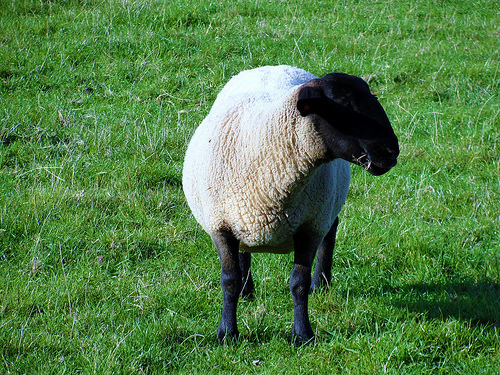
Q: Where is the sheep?
A: In grass.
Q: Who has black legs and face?
A: Sheep.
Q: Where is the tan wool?
A: On sheep.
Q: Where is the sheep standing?
A: In grass field.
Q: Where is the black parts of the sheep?
A: Head and legs.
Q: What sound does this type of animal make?
A: Bleat.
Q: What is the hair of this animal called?
A: Wool.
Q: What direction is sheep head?
A: Right.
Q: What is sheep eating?
A: Grass.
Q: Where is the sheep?
A: On grass.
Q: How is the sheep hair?
A: Shorn.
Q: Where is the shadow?
A: On grass.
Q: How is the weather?
A: Bright.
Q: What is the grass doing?
A: Growing.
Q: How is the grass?
A: Lush.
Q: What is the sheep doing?
A: Standing.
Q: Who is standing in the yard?
A: A sheep.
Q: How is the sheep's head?
A: Black.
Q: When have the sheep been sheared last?
A: A while ago.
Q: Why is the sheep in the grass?
A: Grazing.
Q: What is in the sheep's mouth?
A: Grass.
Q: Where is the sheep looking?
A: To the right.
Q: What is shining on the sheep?
A: Sunlight.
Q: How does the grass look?
A: Healthy.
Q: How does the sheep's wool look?
A: Fluffy.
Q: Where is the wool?
A: On the sheep.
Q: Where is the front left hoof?
A: On the ground.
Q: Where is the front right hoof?
A: On the sheep.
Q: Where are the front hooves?
A: On the sheep.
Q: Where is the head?
A: On the sheep.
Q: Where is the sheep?
A: In the grass.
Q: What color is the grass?
A: Green.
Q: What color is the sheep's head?
A: Black.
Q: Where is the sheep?
A: In a field.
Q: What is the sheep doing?
A: Eating.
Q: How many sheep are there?
A: One.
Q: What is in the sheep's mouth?
A: Grass.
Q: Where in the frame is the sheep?
A: In the center.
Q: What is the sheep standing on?
A: Grass.